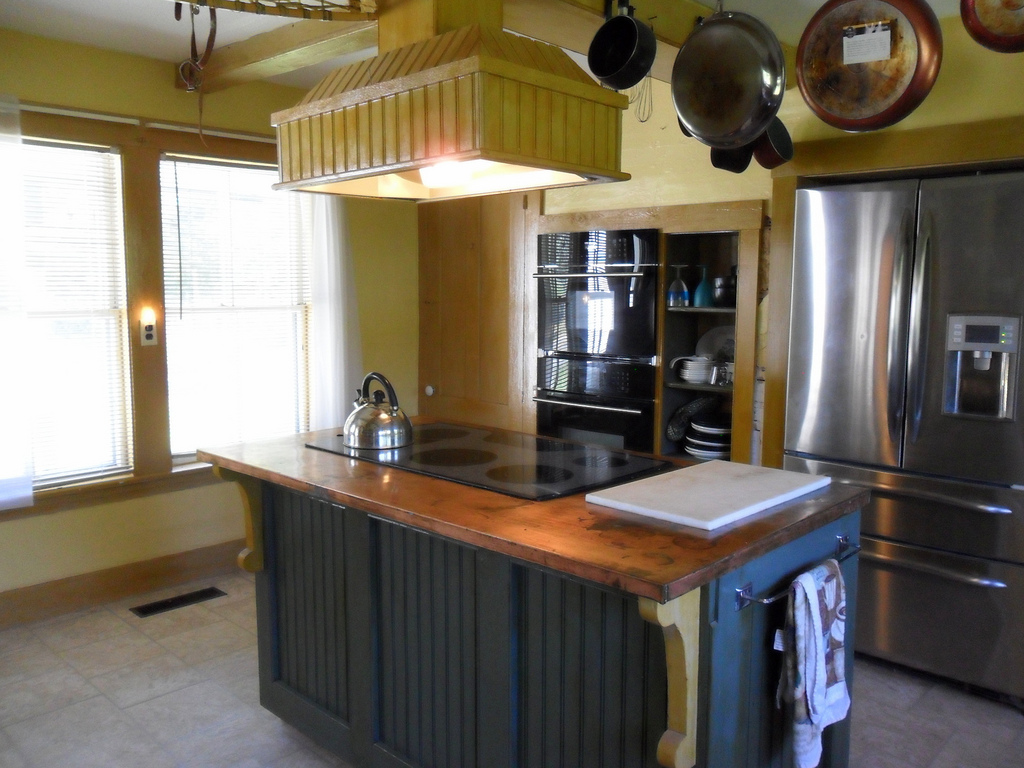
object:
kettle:
[343, 371, 414, 450]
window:
[0, 132, 137, 503]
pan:
[671, 11, 788, 150]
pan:
[792, 0, 942, 132]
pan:
[588, 17, 657, 91]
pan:
[959, 0, 1024, 54]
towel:
[777, 560, 849, 766]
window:
[161, 152, 348, 467]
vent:
[128, 586, 227, 618]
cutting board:
[584, 458, 831, 531]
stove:
[304, 422, 673, 500]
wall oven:
[532, 229, 663, 453]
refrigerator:
[781, 169, 1024, 694]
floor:
[0, 570, 1024, 768]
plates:
[685, 417, 731, 462]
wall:
[0, 0, 1024, 626]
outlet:
[139, 304, 158, 347]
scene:
[0, 126, 332, 488]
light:
[140, 306, 156, 325]